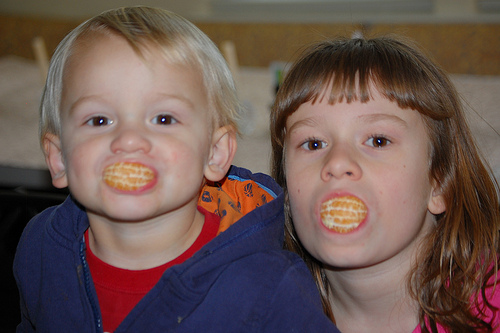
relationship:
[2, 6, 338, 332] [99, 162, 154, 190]
boy holding orange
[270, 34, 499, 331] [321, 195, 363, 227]
child holding orange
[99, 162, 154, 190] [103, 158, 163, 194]
orange in mouth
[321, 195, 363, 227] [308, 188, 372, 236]
orange in mouth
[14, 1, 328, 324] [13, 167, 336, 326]
boy wearing jacket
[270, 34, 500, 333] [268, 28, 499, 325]
child wearing hair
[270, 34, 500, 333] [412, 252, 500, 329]
child wearing dress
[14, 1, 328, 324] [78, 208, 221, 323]
boy wearing shirt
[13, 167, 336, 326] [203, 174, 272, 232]
jacket has lining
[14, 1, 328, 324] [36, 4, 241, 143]
boy with hair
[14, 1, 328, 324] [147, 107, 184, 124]
boy has eye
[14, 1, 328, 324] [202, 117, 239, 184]
boy has ear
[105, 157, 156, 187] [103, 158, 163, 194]
piece in mouth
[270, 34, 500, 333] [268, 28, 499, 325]
child with hair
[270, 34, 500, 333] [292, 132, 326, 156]
child has eye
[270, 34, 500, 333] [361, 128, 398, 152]
child has eye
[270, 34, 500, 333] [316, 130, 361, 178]
child has nose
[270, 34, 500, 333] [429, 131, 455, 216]
child has ear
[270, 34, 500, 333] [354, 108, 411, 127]
child has eyebrow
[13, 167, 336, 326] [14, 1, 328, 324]
jacket on boy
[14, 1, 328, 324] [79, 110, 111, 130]
boy has right eye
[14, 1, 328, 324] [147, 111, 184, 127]
boy has eye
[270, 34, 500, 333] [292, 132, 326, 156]
child has right eye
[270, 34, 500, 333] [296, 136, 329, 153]
child has eye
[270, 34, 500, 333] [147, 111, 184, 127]
child has eye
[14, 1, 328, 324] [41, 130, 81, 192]
boy has left ear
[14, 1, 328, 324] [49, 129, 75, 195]
boy has right ear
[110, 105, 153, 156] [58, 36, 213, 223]
nose on face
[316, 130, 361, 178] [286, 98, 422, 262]
nose on face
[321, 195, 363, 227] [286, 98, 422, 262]
orange in face